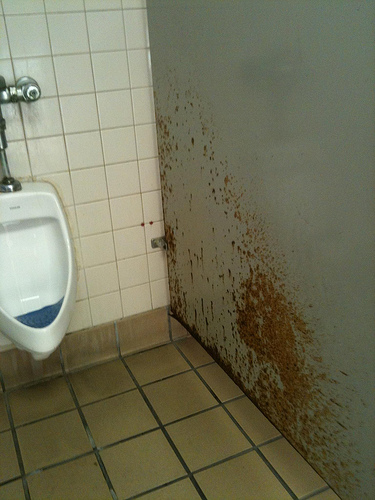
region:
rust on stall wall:
[228, 250, 318, 368]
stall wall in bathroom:
[131, 7, 230, 229]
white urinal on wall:
[8, 172, 94, 365]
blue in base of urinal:
[17, 287, 71, 345]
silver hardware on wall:
[2, 71, 43, 196]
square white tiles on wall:
[78, 102, 142, 201]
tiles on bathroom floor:
[106, 363, 204, 456]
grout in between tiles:
[159, 420, 183, 455]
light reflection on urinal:
[13, 291, 44, 305]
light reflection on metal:
[3, 176, 24, 203]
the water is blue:
[8, 289, 80, 326]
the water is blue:
[16, 289, 80, 364]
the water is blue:
[22, 300, 77, 339]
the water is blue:
[12, 288, 144, 400]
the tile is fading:
[149, 364, 237, 459]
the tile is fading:
[177, 400, 258, 479]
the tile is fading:
[124, 395, 257, 492]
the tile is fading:
[196, 432, 241, 478]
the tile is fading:
[183, 442, 199, 457]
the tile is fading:
[85, 319, 248, 471]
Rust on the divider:
[144, 90, 336, 437]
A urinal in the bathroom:
[10, 181, 64, 355]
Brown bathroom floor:
[81, 367, 214, 483]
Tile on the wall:
[75, 175, 145, 262]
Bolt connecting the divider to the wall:
[142, 220, 168, 255]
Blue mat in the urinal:
[15, 287, 63, 349]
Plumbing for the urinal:
[0, 169, 42, 182]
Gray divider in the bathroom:
[199, 179, 347, 303]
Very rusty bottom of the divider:
[161, 286, 286, 452]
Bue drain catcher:
[28, 299, 58, 331]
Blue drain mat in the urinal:
[12, 303, 65, 337]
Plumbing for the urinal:
[0, 107, 20, 197]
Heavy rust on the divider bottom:
[164, 283, 314, 441]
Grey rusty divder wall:
[250, 127, 321, 244]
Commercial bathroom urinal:
[7, 141, 65, 378]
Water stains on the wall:
[9, 309, 155, 384]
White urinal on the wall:
[6, 164, 88, 358]